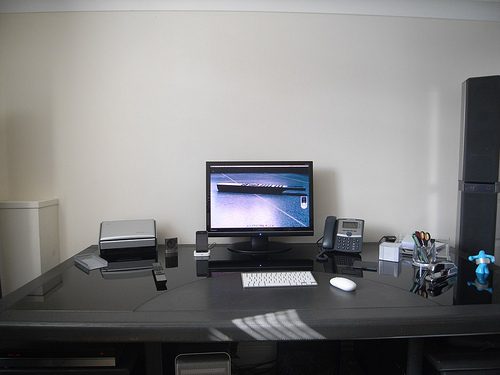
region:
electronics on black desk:
[201, 157, 311, 232]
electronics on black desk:
[93, 219, 163, 253]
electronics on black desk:
[148, 260, 175, 299]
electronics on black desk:
[188, 226, 213, 269]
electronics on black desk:
[230, 252, 317, 298]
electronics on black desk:
[321, 215, 372, 262]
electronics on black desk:
[325, 271, 358, 301]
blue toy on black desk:
[464, 242, 497, 281]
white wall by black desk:
[40, 26, 248, 149]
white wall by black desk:
[233, 33, 452, 153]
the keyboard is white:
[225, 261, 365, 328]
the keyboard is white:
[243, 272, 340, 316]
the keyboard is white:
[237, 247, 314, 335]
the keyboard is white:
[249, 247, 306, 318]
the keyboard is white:
[253, 234, 335, 324]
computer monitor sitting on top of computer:
[203, 161, 314, 254]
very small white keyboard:
[242, 270, 313, 289]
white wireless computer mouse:
[333, 277, 354, 293]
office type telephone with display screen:
[321, 217, 366, 262]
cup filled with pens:
[412, 230, 437, 269]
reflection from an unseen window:
[211, 309, 320, 338]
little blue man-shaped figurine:
[468, 250, 495, 279]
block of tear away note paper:
[379, 241, 403, 261]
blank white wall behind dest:
[21, 42, 467, 233]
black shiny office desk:
[12, 229, 498, 333]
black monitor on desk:
[192, 151, 321, 235]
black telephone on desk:
[321, 210, 365, 260]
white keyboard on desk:
[239, 274, 321, 291]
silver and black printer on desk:
[91, 213, 161, 245]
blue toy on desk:
[468, 248, 496, 276]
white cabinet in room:
[6, 191, 62, 258]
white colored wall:
[8, 24, 258, 145]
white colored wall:
[187, 29, 446, 148]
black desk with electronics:
[38, 285, 224, 325]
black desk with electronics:
[332, 290, 477, 330]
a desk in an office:
[41, 137, 484, 343]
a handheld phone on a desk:
[321, 208, 370, 259]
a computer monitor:
[206, 157, 313, 239]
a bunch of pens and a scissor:
[408, 222, 443, 263]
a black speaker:
[192, 230, 213, 255]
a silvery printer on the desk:
[98, 210, 158, 257]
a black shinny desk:
[43, 285, 333, 333]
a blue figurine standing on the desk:
[467, 237, 497, 279]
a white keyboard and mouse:
[236, 271, 362, 300]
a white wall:
[66, 26, 429, 158]